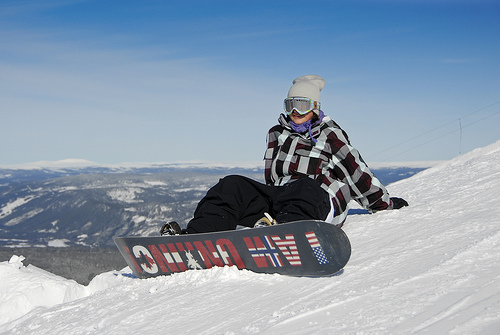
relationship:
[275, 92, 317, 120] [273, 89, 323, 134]
goggle on face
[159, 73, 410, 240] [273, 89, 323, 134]
woman has face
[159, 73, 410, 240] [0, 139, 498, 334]
woman sits in snow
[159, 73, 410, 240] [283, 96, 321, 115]
woman wears goggle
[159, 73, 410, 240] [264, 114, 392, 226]
woman wears shirt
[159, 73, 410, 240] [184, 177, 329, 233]
woman wears pants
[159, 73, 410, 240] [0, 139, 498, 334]
woman in snow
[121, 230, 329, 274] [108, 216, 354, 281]
writing on snowboard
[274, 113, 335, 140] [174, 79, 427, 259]
scarf on snowboarder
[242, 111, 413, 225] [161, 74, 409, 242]
shirt on snowboarder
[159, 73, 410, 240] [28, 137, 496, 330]
woman reclining on snowy slope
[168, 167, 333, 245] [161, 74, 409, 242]
pants on snowboarder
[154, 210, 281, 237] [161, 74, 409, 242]
sneakers on snowboarder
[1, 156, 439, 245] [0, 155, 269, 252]
snow on mountains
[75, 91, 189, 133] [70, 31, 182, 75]
clouds in sky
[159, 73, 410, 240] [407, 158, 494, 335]
woman sitting on snowbank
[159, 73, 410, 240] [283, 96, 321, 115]
woman has on goggle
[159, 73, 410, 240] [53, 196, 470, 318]
woman sitting on snowbank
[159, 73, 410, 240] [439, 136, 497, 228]
woman sitting on snow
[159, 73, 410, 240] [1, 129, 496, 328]
woman sitting on snow bank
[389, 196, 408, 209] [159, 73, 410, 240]
mitten on woman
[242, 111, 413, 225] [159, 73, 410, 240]
shirt on woman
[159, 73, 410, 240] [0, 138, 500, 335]
woman sitting on snowy slope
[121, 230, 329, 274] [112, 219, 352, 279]
writing on snowboard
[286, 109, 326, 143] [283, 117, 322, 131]
scarf around neck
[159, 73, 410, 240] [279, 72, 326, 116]
woman wearing knitted cap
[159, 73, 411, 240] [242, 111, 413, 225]
woman wearing shirt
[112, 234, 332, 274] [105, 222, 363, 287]
writing on snowboard